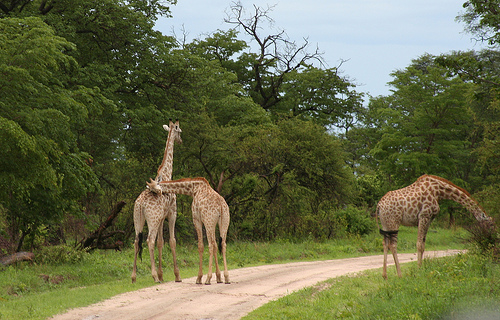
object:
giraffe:
[145, 177, 231, 286]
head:
[147, 179, 162, 196]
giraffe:
[129, 122, 184, 286]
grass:
[1, 253, 87, 307]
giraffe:
[376, 174, 500, 279]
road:
[49, 247, 472, 320]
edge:
[452, 288, 496, 319]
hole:
[438, 293, 498, 319]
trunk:
[1, 250, 33, 268]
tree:
[1, 202, 126, 269]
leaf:
[171, 0, 175, 5]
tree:
[117, 0, 181, 27]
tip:
[137, 232, 143, 260]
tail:
[136, 223, 146, 258]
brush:
[70, 202, 125, 258]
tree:
[200, 0, 347, 118]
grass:
[335, 278, 481, 319]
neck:
[156, 134, 176, 180]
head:
[477, 215, 498, 244]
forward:
[227, 2, 500, 171]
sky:
[152, 1, 497, 98]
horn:
[149, 178, 157, 185]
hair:
[135, 231, 145, 262]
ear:
[163, 125, 170, 131]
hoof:
[205, 275, 212, 286]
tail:
[375, 226, 402, 244]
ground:
[2, 241, 498, 319]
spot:
[34, 270, 63, 289]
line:
[273, 266, 322, 286]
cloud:
[315, 0, 450, 36]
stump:
[2, 246, 41, 267]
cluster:
[0, 17, 90, 82]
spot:
[192, 182, 204, 192]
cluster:
[131, 119, 498, 287]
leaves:
[14, 29, 40, 46]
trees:
[1, 4, 128, 251]